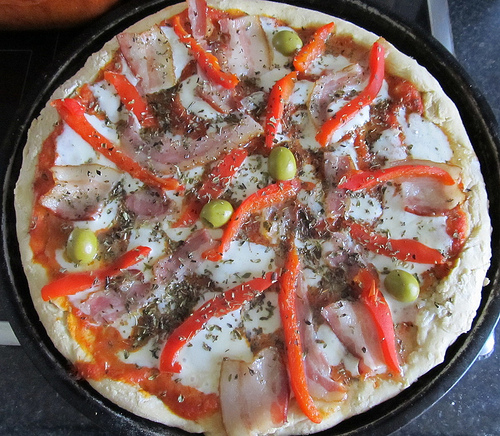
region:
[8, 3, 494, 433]
A small pizza with many toppings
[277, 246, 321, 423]
A slice of red pepper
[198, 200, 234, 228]
A green olive without it's pit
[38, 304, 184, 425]
Crust around the edge of a pizza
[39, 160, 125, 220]
A piece of bacon on the pizza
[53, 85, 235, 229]
Toppings sprinkled with fresh herbs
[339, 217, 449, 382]
Bacon, an olive and sliced red pepper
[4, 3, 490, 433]
A pizza with bacon, red peppers and olives as toppings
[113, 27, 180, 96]
A small piece of bacon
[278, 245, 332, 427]
red bell pepper slice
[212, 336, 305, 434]
a slice of bacon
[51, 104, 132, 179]
white mozzerella cheese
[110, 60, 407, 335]
sprinkled basil seasoning throughout pizza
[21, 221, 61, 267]
red tomato pizza sauce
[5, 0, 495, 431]
a black metal pizza pan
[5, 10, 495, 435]
a uncooked pizza crust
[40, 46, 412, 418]
Pizza in a pan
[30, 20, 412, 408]
Pizza in a pan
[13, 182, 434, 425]
Pizza in a pan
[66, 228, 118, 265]
Olives on a pizza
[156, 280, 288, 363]
peppers on a pizza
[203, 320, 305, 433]
bacon on a pizza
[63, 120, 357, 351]
seasoning on a pizza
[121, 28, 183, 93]
bacon on the pizza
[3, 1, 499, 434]
pan has pizza in it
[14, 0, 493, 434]
pizza sits in pan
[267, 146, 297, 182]
olive is on pizza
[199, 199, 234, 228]
olive is on pizza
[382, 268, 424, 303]
olive is on pizza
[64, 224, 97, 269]
olive is on pizza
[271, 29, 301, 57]
olive is on pizza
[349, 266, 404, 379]
bell pepper is on pizza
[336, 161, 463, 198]
bell pepper is on pizza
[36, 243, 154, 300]
bell pepper is on pizza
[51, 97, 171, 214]
peppers on a pizza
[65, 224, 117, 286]
olives on a pizza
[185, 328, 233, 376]
cheese on a pizza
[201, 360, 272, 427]
bacon on a pizza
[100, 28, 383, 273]
Bacon on top of a pizza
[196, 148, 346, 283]
olives and peppers on a pizza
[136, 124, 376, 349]
oregano on a pizza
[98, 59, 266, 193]
bacon and ham on a pizza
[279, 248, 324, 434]
the peppers are red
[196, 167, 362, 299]
seasonings on the pizza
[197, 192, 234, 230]
the olives are green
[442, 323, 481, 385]
the tray is black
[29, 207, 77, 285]
the sauce is on the pizza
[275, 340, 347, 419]
pepper is on the bacon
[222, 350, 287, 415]
the bacon is raw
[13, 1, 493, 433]
large white doughy pizza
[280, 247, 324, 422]
long thin orange vegetable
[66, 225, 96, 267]
small round green olive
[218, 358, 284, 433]
large thin slice of meat